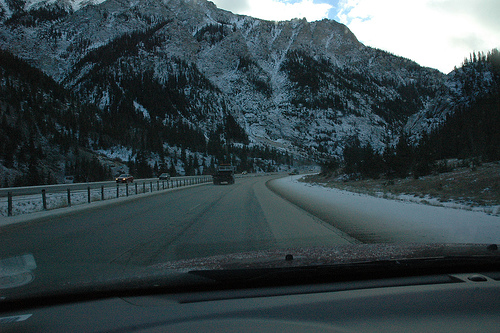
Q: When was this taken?
A: Daytime.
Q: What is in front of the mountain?
A: Another car.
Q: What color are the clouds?
A: White.